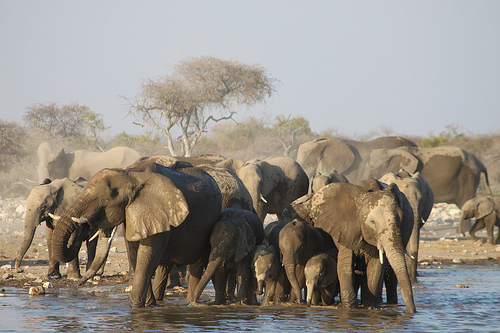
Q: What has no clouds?
A: The sky.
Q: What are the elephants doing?
A: Bathing in the water.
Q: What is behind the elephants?
A: Tall trees.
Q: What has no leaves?
A: Trees.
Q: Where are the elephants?
A: In water.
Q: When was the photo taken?
A: During the daytime.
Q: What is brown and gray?
A: The elephant.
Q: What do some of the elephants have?
A: Tusks.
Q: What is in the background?
A: Trees.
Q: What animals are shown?
A: Elephants.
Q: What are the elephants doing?
A: Drinking water.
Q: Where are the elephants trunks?
A: In the water.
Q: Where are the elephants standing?
A: In the water.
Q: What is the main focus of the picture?
A: The elephants.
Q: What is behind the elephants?
A: Trees.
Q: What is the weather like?
A: Sunny.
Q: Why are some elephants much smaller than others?
A: Babies.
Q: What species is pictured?
A: Elephant.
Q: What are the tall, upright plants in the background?
A: Trees.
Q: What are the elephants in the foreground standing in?
A: Water.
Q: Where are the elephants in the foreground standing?
A: River.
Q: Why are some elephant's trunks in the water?
A: Drinking.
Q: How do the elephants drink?
A: With their trunks.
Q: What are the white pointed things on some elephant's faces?
A: Tusks.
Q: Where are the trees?
A: Behind the elephants.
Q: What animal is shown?
A: Elephants.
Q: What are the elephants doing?
A: Drinking water.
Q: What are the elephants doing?
A: Drinking water.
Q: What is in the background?
A: Trees.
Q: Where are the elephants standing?
A: In the water.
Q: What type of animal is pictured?
A: Elephants.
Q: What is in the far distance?
A: Trees.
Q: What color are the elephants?
A: Gray.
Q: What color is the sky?
A: Dusty blue.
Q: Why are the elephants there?
A: Drinking water and staying cool.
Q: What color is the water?
A: Blue.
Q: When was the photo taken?
A: In the daytime.